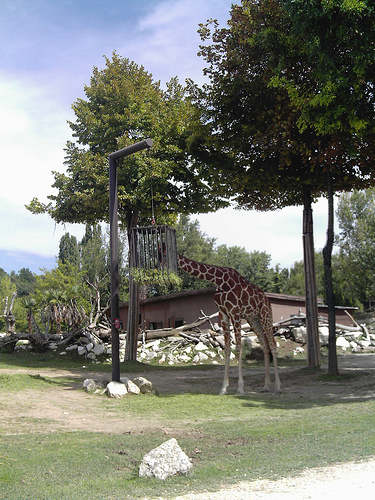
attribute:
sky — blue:
[91, 8, 116, 24]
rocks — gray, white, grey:
[106, 382, 139, 398]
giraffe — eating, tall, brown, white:
[153, 244, 283, 387]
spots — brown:
[240, 293, 249, 305]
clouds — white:
[29, 87, 48, 98]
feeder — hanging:
[125, 234, 171, 271]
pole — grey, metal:
[109, 165, 119, 386]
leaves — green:
[297, 40, 308, 49]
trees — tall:
[146, 89, 291, 137]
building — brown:
[179, 300, 198, 319]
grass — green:
[98, 451, 104, 458]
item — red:
[114, 320, 122, 328]